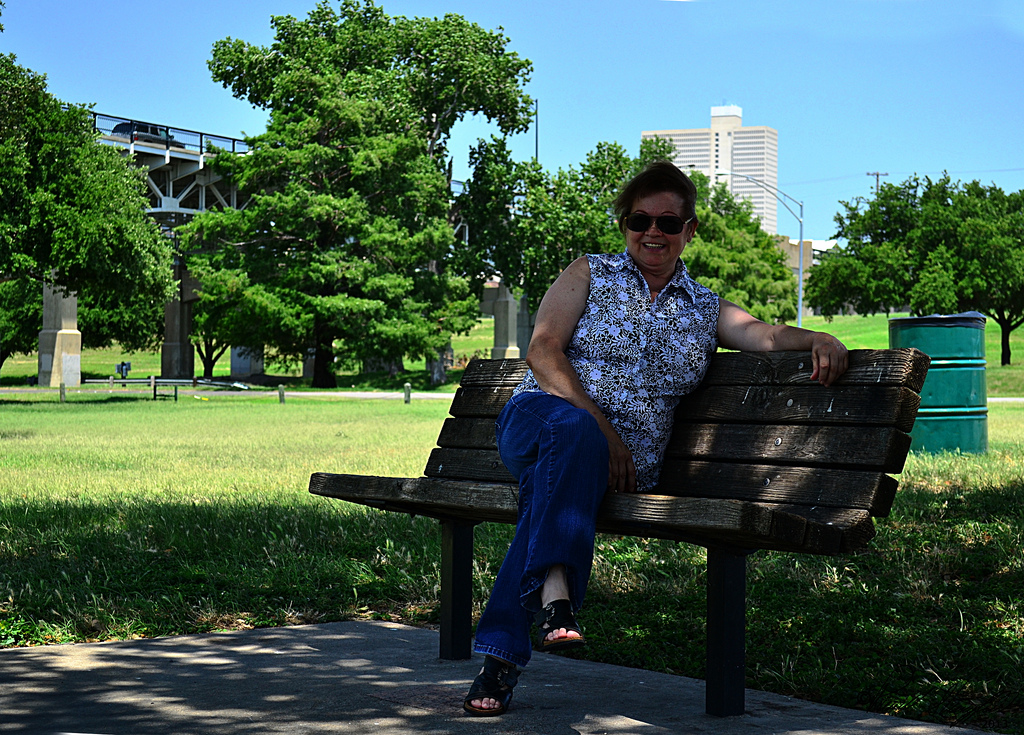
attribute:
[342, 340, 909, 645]
bench — brown, wooden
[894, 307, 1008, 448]
trash bin — green, circular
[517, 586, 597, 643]
sandal — black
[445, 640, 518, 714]
sandal — black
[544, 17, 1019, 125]
blue sky — cloudless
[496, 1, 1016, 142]
blue sky — cloudless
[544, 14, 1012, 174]
blue sky — cloudless